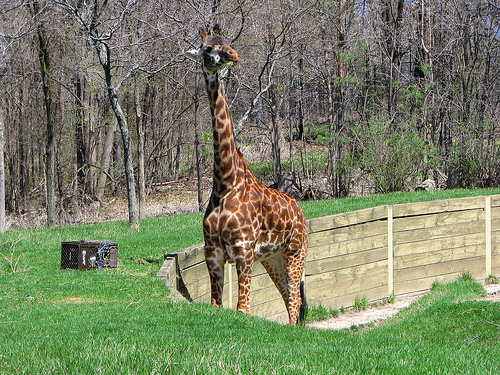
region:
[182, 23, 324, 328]
Adult giraffe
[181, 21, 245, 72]
The head of an adult giraffe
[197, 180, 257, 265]
The chest of an adult giraffe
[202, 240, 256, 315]
The front legs of an adult giraffe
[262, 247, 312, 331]
The back legs of an adult giraffe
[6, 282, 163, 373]
Green gras with some dirt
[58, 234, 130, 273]
Empty crate laying sideways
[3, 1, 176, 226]
Many leafless trees in background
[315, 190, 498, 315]
Wooden retaining wall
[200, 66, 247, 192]
Long neck of adult giraffe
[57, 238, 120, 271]
milk crate on the ground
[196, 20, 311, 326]
giraffe standing in enclosure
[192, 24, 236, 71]
giraffe is eating something green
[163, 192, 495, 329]
enclosure made of wooden boards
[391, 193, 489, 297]
fence is made up of seven board per sections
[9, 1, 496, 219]
the trees are mostly bare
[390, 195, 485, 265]
wood is light brown of enclosure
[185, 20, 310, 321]
giraffe is brown and tan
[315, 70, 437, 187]
some trees or bushes have green leaves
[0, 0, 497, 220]
trees are small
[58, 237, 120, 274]
A small brown milk crate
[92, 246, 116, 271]
Blue cloth on the brown crate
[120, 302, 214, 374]
The grass is cut short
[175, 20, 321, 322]
The giraffe is yellow and brown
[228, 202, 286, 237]
The giraffe has spots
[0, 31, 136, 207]
A forest in the distance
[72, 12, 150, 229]
A thin, dying tree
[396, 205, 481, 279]
Brown wooden planks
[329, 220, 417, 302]
The wood is unpolished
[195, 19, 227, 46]
The giraffe has two horns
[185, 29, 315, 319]
The giraffe is brown and yellow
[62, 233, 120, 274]
A brown milk crate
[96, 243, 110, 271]
Blue cloth on the crate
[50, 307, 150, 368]
Short green grass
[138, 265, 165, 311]
Grass near the edge of the containment area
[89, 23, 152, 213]
A dead tree behind the giraffe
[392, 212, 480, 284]
Wooden planks near the animal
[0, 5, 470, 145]
A forest in the distance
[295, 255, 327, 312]
A drooping tail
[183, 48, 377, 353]
tall and brown giraffe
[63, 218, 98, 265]
brown box on grass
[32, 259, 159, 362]
grass is short and green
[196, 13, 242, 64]
giraffe has dark head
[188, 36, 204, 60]
giraffe has light ears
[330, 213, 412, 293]
light brown wood fence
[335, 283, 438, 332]
light dirt patches on ground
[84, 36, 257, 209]
thin and bare trees behind giraffe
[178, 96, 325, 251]
brown and orange spots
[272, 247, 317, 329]
brown spotted legs on giraffe